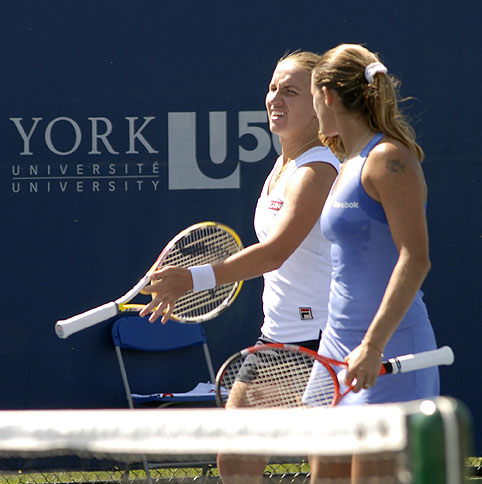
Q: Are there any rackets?
A: Yes, there is a racket.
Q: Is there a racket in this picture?
A: Yes, there is a racket.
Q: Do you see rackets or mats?
A: Yes, there is a racket.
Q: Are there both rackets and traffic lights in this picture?
A: No, there is a racket but no traffic lights.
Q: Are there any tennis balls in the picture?
A: No, there are no tennis balls.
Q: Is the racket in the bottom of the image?
A: Yes, the racket is in the bottom of the image.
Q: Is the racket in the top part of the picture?
A: No, the racket is in the bottom of the image.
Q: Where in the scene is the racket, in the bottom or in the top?
A: The racket is in the bottom of the image.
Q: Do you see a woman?
A: Yes, there is a woman.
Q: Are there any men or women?
A: Yes, there is a woman.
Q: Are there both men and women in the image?
A: No, there is a woman but no men.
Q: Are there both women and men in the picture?
A: No, there is a woman but no men.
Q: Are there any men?
A: No, there are no men.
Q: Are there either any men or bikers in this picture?
A: No, there are no men or bikers.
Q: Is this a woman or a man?
A: This is a woman.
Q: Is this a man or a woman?
A: This is a woman.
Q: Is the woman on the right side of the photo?
A: Yes, the woman is on the right of the image.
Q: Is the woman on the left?
A: No, the woman is on the right of the image.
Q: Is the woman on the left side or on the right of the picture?
A: The woman is on the right of the image.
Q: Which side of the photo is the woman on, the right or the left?
A: The woman is on the right of the image.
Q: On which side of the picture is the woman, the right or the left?
A: The woman is on the right of the image.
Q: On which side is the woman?
A: The woman is on the right of the image.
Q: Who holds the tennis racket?
A: The woman holds the tennis racket.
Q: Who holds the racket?
A: The woman holds the tennis racket.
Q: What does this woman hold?
A: The woman holds the racket.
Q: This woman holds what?
A: The woman holds the racket.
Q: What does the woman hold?
A: The woman holds the racket.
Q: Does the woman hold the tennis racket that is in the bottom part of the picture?
A: Yes, the woman holds the racket.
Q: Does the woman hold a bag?
A: No, the woman holds the racket.